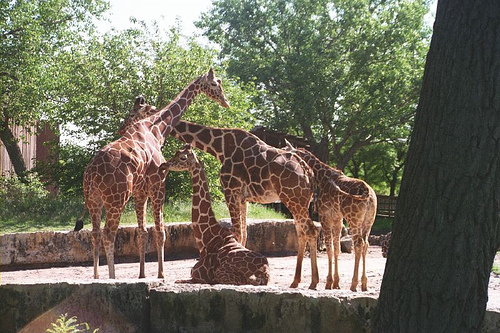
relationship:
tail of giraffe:
[71, 166, 98, 236] [72, 63, 235, 280]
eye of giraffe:
[178, 152, 189, 163] [157, 144, 274, 288]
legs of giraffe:
[86, 205, 166, 286] [72, 63, 235, 280]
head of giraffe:
[157, 141, 206, 181] [157, 144, 274, 288]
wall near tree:
[0, 227, 70, 271] [1, 3, 111, 186]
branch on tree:
[2, 50, 60, 172] [1, 3, 111, 186]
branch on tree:
[6, 19, 96, 178] [1, 3, 111, 186]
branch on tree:
[6, 46, 92, 172] [1, 3, 111, 186]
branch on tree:
[4, 34, 90, 167] [1, 3, 111, 186]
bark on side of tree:
[425, 142, 454, 166] [1, 3, 111, 186]